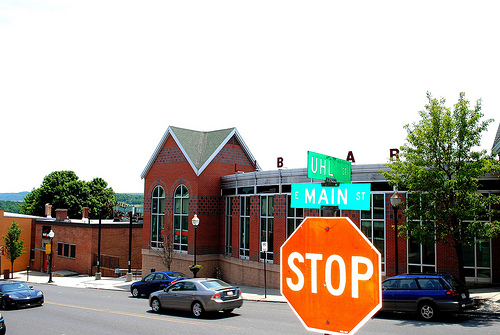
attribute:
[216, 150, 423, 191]
roof — curved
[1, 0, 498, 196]
sky — clear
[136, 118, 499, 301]
building — brick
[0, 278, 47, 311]
corvette — black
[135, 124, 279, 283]
building — brick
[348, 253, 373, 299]
letter — white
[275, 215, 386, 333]
sign — red, bright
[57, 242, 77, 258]
three windows — black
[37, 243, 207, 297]
sidewalk — brick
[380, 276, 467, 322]
station wagon — blue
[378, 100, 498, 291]
leaves — green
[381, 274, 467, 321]
car — blue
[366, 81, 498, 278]
leaves — green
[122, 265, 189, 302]
sedan — parked, blue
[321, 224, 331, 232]
bolt — metal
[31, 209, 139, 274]
building — red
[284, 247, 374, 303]
letters — white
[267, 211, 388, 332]
stop sign — red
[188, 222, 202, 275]
pole — black